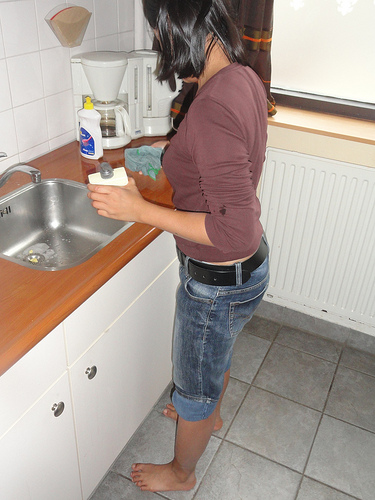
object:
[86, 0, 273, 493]
woman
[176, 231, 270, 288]
belt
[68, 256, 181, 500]
door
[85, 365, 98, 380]
knob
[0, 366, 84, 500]
door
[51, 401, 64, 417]
knob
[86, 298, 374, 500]
tiled floor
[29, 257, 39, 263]
item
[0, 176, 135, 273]
sink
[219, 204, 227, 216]
stain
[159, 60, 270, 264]
shirt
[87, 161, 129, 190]
soap dispenser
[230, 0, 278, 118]
curtains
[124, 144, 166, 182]
rag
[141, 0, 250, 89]
hair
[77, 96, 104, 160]
bottle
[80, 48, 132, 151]
coffee maker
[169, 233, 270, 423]
jeans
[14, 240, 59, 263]
soapy water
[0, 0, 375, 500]
kitchen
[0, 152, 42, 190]
faucet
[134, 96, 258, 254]
left arm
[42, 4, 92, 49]
coffee filter holder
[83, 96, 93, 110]
lid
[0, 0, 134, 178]
wall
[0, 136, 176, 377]
couter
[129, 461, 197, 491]
barefeet